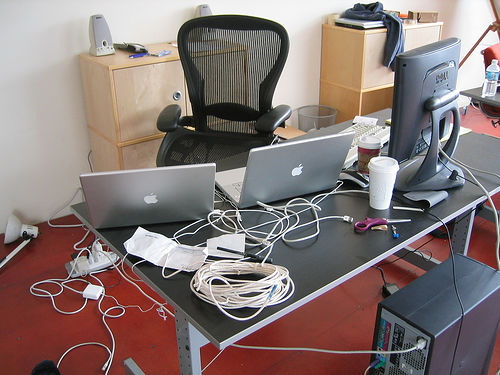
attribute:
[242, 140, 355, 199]
laptop — silver, gray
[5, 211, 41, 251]
lamp — white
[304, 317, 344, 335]
floor — red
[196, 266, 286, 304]
cord — white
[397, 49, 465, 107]
computer monitor — black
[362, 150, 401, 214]
coffee cup — white, styrofoam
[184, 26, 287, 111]
chair — black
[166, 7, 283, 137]
desk chair — black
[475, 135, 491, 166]
desk — black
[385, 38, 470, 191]
desktop — dell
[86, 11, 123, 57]
speakers — gray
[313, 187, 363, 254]
wires — white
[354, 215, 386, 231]
handle — purple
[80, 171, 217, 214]
monitor — gray, black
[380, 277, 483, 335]
computer box — gray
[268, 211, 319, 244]
wire — white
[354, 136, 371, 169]
coffee cup — brown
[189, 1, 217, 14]
speaker — gray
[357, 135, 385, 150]
top — white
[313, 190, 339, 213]
cords — white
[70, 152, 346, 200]
laptops — silver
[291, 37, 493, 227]
desk computers — black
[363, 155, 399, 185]
cup — white